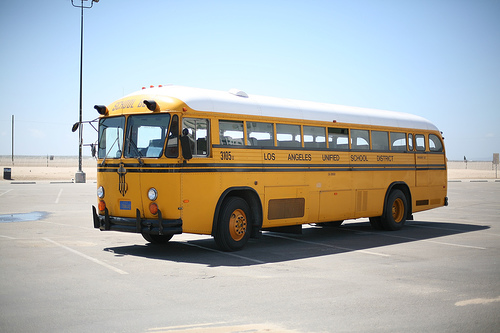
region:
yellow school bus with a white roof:
[70, 83, 450, 251]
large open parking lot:
[1, 178, 498, 331]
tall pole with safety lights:
[68, 0, 98, 183]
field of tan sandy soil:
[1, 154, 498, 179]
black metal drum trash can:
[3, 165, 13, 181]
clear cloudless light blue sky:
[1, 0, 498, 161]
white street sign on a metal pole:
[491, 148, 498, 177]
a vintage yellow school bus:
[70, 83, 450, 248]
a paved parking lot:
[0, 180, 498, 331]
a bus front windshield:
[125, 113, 170, 155]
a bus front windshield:
[99, 115, 125, 157]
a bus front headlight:
[145, 188, 155, 200]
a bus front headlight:
[96, 184, 102, 196]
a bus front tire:
[215, 197, 251, 249]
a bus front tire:
[370, 187, 408, 231]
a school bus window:
[220, 117, 243, 145]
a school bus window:
[245, 118, 273, 146]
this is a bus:
[68, 48, 470, 254]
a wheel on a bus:
[210, 196, 273, 247]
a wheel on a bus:
[357, 172, 423, 243]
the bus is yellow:
[75, 80, 470, 240]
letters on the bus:
[214, 142, 236, 166]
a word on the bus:
[254, 137, 289, 167]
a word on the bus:
[276, 135, 317, 173]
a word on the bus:
[311, 148, 353, 173]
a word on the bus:
[360, 145, 400, 173]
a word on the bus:
[340, 145, 377, 175]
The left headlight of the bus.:
[98, 184, 103, 196]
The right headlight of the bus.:
[147, 189, 157, 199]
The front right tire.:
[219, 199, 256, 245]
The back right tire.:
[375, 188, 407, 233]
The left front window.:
[95, 116, 123, 156]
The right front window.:
[127, 113, 167, 160]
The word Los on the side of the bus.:
[259, 149, 276, 161]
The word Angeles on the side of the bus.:
[285, 154, 312, 160]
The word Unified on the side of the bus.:
[317, 152, 340, 162]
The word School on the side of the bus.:
[351, 152, 369, 161]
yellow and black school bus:
[75, 82, 449, 252]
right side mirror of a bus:
[70, 114, 98, 132]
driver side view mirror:
[168, 127, 192, 162]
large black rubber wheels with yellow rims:
[212, 195, 252, 250]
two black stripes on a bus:
[95, 85, 446, 252]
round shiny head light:
[144, 186, 160, 202]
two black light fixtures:
[91, 98, 158, 115]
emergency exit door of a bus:
[410, 128, 432, 186]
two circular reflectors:
[94, 198, 159, 215]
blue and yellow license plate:
[116, 198, 132, 213]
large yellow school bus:
[67, 78, 455, 260]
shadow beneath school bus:
[100, 217, 494, 269]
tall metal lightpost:
[67, 1, 102, 186]